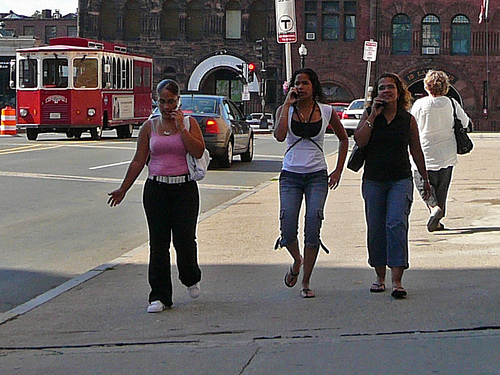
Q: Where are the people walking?
A: On the sidewalk.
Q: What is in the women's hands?
A: Phones.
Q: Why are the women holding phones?
A: To talk.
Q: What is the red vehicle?
A: A bus.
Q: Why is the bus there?
A: To transport people.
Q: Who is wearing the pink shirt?
A: The woman on the left.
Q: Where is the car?
A: Behind the women.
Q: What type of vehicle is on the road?
A: A car.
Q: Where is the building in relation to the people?
A: Behind them.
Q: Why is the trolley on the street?
A: Transporting people.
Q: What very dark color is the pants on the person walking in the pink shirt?
A: Black.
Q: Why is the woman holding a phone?
A: To talk.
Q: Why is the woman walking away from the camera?
A: She is going another direction.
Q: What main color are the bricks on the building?
A: Red.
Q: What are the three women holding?
A: Cell phones.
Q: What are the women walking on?
A: A sidewalk.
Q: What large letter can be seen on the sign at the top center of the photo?
A: The letter T.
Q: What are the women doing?
A: Walking down the street.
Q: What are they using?
A: They are using their phones.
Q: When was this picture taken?
A: During the day.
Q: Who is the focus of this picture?
A: Three women.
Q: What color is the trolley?
A: Red and white.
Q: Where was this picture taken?
A: On a sidewalk.